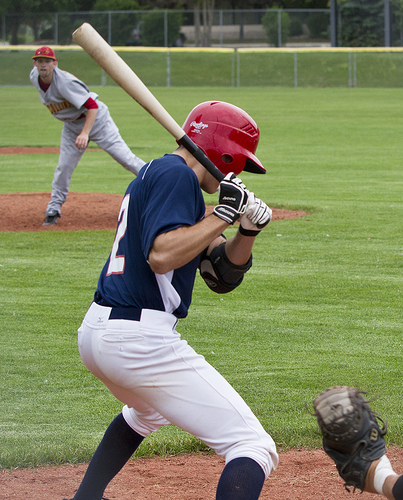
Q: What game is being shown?
A: Baseball.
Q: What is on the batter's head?
A: Helmet.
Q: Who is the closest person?
A: A batter.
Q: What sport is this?
A: Baseball.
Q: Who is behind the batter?
A: The catcher.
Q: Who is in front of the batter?
A: The pitcher.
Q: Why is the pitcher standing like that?
A: To throw the ball.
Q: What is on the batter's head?
A: A helmet.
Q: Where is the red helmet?
A: On the batter's head.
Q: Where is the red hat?
A: ON the pitcher's head.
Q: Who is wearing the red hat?
A: The pitcher.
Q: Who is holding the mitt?
A: The catcher.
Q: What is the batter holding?
A: A baseball bat.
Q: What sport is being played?
A: Baseball.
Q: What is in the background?
A: Fence.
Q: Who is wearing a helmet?
A: The batter.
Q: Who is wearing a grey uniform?
A: The pitcher.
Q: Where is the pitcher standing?
A: The pitcher's mound.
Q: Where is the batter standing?
A: Home plate.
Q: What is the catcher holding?
A: Glove.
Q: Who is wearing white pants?
A: The batter.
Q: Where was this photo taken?
A: A baseball field.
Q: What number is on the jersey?
A: Two.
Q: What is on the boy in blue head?
A: Helmet.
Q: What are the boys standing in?
A: Dirt.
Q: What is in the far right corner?
A: Baseball mitt.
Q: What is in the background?
A: Chain link fence.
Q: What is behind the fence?
A: Trees.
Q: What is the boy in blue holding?
A: Baseball bat.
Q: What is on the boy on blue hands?
A: Gloves.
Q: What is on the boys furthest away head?
A: Baseball cap.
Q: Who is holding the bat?
A: The batter.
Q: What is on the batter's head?
A: A red helmet.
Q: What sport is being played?
A: Baseball.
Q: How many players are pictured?
A: Two.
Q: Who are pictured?
A: Baseball players.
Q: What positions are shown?
A: Pitcher and batter.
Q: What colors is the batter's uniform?
A: Red, white and blue.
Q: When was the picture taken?
A: Daytime.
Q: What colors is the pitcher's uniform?
A: Grey and red.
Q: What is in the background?
A: Fence.